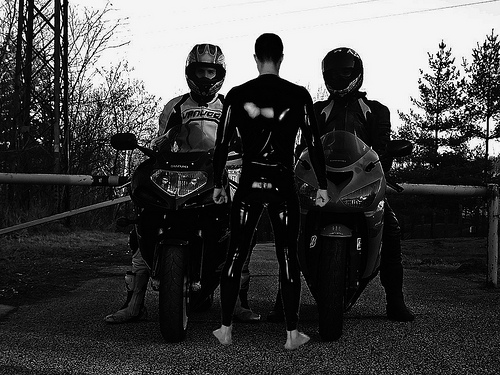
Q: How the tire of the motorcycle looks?
A: Good.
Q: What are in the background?
A: Trees.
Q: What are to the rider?
A: Boots.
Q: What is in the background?
A: The sky.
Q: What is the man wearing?
A: A black rubber suit.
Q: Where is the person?
A: Sitting on the motorcycle.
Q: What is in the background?
A: A wooden log barrier fence.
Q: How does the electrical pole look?
A: It is grey and metal.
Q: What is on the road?
A: An evergreen tree.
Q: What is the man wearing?
A: A black suit.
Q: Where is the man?
A: On a motorcycle.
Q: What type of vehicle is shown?
A: A motorcycle.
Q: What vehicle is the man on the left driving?
A: A motorcycle.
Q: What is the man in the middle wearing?
A: A full body suit.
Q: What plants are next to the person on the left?
A: Trees.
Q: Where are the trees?
A: Behind the bikers.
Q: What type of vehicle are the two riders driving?
A: Motorcycles.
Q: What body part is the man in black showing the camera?
A: Back.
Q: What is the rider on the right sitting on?
A: A motorcycle.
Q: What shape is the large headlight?
A: Triangle.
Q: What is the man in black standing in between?
A: Motorcycles.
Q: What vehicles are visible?
A: Motorbikes.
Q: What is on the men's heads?
A: Helmets.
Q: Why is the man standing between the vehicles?
A: To start the race.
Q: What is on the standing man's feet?
A: Nothing.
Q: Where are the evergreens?
A: Background to the right.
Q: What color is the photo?
A: Black and white.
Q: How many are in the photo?
A: Three.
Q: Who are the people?
A: Bikers.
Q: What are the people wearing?
A: Helmets.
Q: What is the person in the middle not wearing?
A: A helmet.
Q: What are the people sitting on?
A: Bikes.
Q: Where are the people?
A: In the woods.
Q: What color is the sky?
A: White.